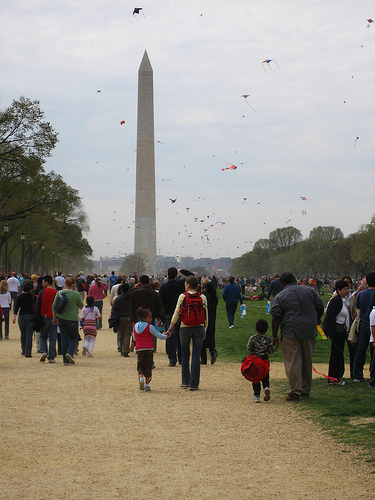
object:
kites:
[220, 157, 236, 175]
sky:
[0, 0, 375, 265]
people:
[52, 275, 83, 365]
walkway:
[0, 276, 375, 500]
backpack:
[176, 291, 210, 329]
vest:
[132, 328, 158, 353]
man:
[269, 270, 326, 403]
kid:
[246, 315, 279, 401]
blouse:
[52, 285, 84, 320]